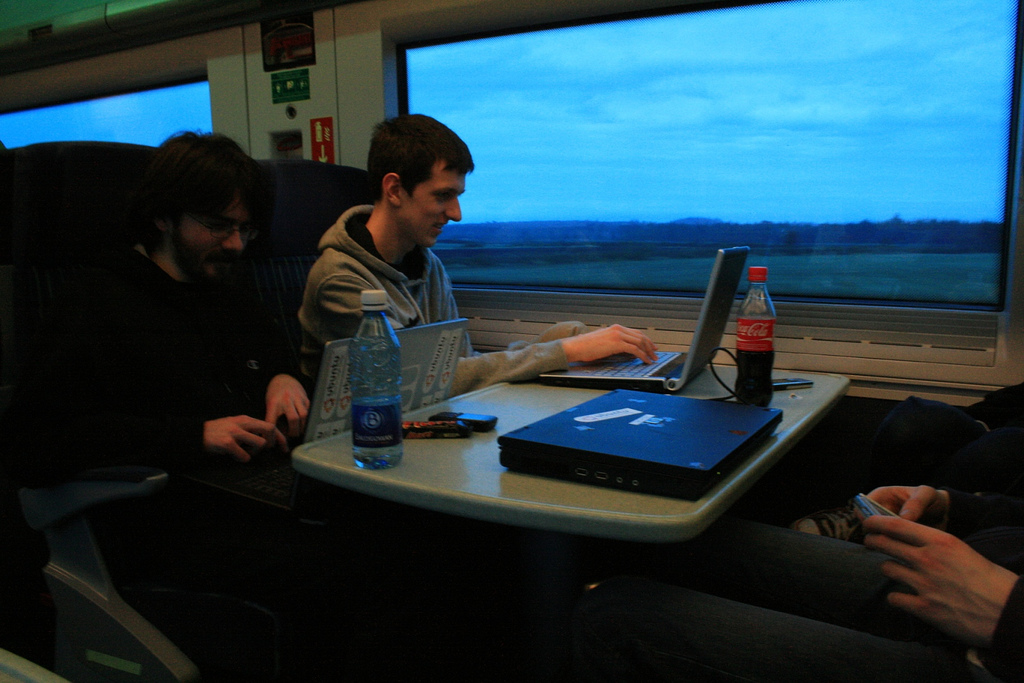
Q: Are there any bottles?
A: Yes, there is a bottle.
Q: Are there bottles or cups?
A: Yes, there is a bottle.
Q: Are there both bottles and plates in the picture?
A: No, there is a bottle but no plates.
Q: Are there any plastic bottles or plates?
A: Yes, there is a plastic bottle.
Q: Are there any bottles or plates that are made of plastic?
A: Yes, the bottle is made of plastic.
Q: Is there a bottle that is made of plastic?
A: Yes, there is a bottle that is made of plastic.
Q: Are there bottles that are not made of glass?
A: Yes, there is a bottle that is made of plastic.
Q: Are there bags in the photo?
A: No, there are no bags.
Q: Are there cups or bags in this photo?
A: No, there are no bags or cups.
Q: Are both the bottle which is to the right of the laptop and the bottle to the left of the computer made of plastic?
A: Yes, both the bottle and the bottle are made of plastic.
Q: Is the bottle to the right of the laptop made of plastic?
A: Yes, the bottle is made of plastic.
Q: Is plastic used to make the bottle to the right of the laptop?
A: Yes, the bottle is made of plastic.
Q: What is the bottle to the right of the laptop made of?
A: The bottle is made of plastic.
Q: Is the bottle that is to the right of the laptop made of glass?
A: No, the bottle is made of plastic.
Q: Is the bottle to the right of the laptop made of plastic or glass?
A: The bottle is made of plastic.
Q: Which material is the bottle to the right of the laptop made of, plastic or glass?
A: The bottle is made of plastic.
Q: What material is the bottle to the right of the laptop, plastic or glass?
A: The bottle is made of plastic.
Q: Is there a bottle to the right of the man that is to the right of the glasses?
A: Yes, there is a bottle to the right of the man.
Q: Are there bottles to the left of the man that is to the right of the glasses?
A: No, the bottle is to the right of the man.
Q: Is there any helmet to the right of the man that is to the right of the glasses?
A: No, there is a bottle to the right of the man.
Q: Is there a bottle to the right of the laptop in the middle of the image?
A: Yes, there is a bottle to the right of the laptop.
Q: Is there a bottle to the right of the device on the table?
A: Yes, there is a bottle to the right of the laptop.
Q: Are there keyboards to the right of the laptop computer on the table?
A: No, there is a bottle to the right of the laptop.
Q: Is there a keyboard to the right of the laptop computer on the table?
A: No, there is a bottle to the right of the laptop.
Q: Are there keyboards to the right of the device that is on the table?
A: No, there is a bottle to the right of the laptop.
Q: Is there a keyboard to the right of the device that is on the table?
A: No, there is a bottle to the right of the laptop.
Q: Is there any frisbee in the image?
A: No, there are no frisbees.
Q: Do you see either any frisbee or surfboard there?
A: No, there are no frisbees or surfboards.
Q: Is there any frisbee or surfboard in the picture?
A: No, there are no frisbees or surfboards.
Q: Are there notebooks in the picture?
A: No, there are no notebooks.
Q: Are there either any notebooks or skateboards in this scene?
A: No, there are no notebooks or skateboards.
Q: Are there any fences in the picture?
A: No, there are no fences.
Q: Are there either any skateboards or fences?
A: No, there are no fences or skateboards.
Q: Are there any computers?
A: Yes, there is a computer.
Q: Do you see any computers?
A: Yes, there is a computer.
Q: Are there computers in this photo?
A: Yes, there is a computer.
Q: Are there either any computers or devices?
A: Yes, there is a computer.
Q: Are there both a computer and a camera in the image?
A: No, there is a computer but no cameras.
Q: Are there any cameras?
A: No, there are no cameras.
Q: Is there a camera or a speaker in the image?
A: No, there are no cameras or speakers.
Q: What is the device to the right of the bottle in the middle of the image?
A: The device is a computer.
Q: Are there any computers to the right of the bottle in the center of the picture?
A: Yes, there is a computer to the right of the bottle.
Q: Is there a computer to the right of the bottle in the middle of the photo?
A: Yes, there is a computer to the right of the bottle.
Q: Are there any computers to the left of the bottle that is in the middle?
A: No, the computer is to the right of the bottle.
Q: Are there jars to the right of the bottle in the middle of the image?
A: No, there is a computer to the right of the bottle.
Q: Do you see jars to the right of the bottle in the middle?
A: No, there is a computer to the right of the bottle.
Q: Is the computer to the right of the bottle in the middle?
A: Yes, the computer is to the right of the bottle.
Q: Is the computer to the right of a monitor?
A: No, the computer is to the right of the bottle.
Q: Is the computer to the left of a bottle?
A: No, the computer is to the right of a bottle.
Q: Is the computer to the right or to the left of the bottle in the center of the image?
A: The computer is to the right of the bottle.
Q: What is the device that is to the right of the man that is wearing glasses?
A: The device is a computer.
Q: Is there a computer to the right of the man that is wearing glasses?
A: Yes, there is a computer to the right of the man.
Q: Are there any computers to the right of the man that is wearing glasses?
A: Yes, there is a computer to the right of the man.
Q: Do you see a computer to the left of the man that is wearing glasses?
A: No, the computer is to the right of the man.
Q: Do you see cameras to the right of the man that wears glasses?
A: No, there is a computer to the right of the man.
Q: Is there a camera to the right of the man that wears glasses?
A: No, there is a computer to the right of the man.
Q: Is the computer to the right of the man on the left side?
A: Yes, the computer is to the right of the man.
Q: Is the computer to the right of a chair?
A: No, the computer is to the right of the man.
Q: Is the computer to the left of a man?
A: No, the computer is to the right of a man.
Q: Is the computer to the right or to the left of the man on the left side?
A: The computer is to the right of the man.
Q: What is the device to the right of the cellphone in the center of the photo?
A: The device is a computer.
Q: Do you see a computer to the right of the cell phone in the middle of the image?
A: Yes, there is a computer to the right of the cellphone.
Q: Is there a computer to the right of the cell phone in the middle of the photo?
A: Yes, there is a computer to the right of the cellphone.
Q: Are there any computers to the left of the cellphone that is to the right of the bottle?
A: No, the computer is to the right of the cellphone.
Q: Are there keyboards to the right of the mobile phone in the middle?
A: No, there is a computer to the right of the cellphone.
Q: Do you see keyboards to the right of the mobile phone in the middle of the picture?
A: No, there is a computer to the right of the cellphone.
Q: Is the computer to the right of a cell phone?
A: Yes, the computer is to the right of a cell phone.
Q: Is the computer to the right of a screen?
A: No, the computer is to the right of a cell phone.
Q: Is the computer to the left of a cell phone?
A: No, the computer is to the right of a cell phone.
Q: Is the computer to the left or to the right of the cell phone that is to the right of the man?
A: The computer is to the right of the mobile phone.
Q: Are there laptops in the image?
A: Yes, there is a laptop.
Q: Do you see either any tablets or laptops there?
A: Yes, there is a laptop.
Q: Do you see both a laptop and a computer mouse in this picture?
A: No, there is a laptop but no computer mice.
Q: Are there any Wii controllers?
A: No, there are no Wii controllers.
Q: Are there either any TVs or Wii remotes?
A: No, there are no Wii remotes or tvs.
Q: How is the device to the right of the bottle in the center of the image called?
A: The device is a laptop.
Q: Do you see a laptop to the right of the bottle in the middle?
A: Yes, there is a laptop to the right of the bottle.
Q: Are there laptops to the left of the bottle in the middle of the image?
A: No, the laptop is to the right of the bottle.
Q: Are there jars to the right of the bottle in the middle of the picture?
A: No, there is a laptop to the right of the bottle.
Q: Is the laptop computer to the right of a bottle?
A: Yes, the laptop computer is to the right of a bottle.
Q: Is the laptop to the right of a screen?
A: No, the laptop is to the right of a bottle.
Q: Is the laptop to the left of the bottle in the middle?
A: No, the laptop is to the right of the bottle.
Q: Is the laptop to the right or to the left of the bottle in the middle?
A: The laptop is to the right of the bottle.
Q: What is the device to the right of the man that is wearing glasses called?
A: The device is a laptop.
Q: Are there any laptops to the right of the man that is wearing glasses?
A: Yes, there is a laptop to the right of the man.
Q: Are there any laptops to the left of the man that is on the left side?
A: No, the laptop is to the right of the man.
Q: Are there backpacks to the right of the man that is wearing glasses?
A: No, there is a laptop to the right of the man.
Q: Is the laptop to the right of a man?
A: Yes, the laptop is to the right of a man.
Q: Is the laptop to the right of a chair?
A: No, the laptop is to the right of a man.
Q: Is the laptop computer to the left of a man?
A: No, the laptop computer is to the right of a man.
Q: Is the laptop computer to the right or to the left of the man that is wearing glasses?
A: The laptop computer is to the right of the man.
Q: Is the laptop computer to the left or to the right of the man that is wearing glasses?
A: The laptop computer is to the right of the man.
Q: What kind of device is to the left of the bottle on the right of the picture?
A: The device is a laptop.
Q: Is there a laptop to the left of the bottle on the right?
A: Yes, there is a laptop to the left of the bottle.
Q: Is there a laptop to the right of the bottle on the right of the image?
A: No, the laptop is to the left of the bottle.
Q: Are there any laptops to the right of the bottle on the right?
A: No, the laptop is to the left of the bottle.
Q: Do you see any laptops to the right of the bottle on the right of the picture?
A: No, the laptop is to the left of the bottle.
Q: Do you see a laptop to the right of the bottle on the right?
A: No, the laptop is to the left of the bottle.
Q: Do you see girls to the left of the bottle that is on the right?
A: No, there is a laptop to the left of the bottle.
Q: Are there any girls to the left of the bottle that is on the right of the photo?
A: No, there is a laptop to the left of the bottle.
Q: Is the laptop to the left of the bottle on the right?
A: Yes, the laptop is to the left of the bottle.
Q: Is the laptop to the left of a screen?
A: No, the laptop is to the left of the bottle.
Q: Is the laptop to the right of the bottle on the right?
A: No, the laptop is to the left of the bottle.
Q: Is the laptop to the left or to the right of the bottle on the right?
A: The laptop is to the left of the bottle.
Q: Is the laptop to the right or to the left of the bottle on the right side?
A: The laptop is to the left of the bottle.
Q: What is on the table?
A: The laptop is on the table.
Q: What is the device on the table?
A: The device is a laptop.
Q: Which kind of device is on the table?
A: The device is a laptop.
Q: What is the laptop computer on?
A: The laptop computer is on the table.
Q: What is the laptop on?
A: The laptop computer is on the table.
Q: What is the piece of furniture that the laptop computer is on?
A: The piece of furniture is a table.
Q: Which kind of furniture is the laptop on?
A: The laptop computer is on the table.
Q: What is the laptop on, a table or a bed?
A: The laptop is on a table.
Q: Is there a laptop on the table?
A: Yes, there is a laptop on the table.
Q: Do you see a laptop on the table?
A: Yes, there is a laptop on the table.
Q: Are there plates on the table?
A: No, there is a laptop on the table.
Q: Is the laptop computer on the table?
A: Yes, the laptop computer is on the table.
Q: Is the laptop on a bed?
A: No, the laptop is on the table.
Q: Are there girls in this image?
A: No, there are no girls.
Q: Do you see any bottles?
A: Yes, there is a bottle.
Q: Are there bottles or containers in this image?
A: Yes, there is a bottle.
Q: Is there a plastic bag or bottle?
A: Yes, there is a plastic bottle.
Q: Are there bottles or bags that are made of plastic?
A: Yes, the bottle is made of plastic.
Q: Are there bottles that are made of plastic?
A: Yes, there is a bottle that is made of plastic.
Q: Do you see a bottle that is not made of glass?
A: Yes, there is a bottle that is made of plastic.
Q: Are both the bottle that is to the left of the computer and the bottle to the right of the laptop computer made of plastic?
A: Yes, both the bottle and the bottle are made of plastic.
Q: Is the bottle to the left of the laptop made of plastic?
A: Yes, the bottle is made of plastic.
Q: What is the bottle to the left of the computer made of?
A: The bottle is made of plastic.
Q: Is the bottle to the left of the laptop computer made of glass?
A: No, the bottle is made of plastic.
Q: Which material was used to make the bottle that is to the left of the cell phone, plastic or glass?
A: The bottle is made of plastic.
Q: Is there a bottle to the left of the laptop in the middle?
A: Yes, there is a bottle to the left of the laptop.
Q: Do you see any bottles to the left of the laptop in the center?
A: Yes, there is a bottle to the left of the laptop.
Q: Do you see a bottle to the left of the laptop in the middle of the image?
A: Yes, there is a bottle to the left of the laptop.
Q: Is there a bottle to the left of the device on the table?
A: Yes, there is a bottle to the left of the laptop.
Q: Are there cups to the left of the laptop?
A: No, there is a bottle to the left of the laptop.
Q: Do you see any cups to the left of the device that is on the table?
A: No, there is a bottle to the left of the laptop.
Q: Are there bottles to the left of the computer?
A: Yes, there is a bottle to the left of the computer.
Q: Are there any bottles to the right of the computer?
A: No, the bottle is to the left of the computer.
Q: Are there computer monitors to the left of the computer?
A: No, there is a bottle to the left of the computer.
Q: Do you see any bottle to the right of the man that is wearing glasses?
A: Yes, there is a bottle to the right of the man.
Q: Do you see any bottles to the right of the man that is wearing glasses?
A: Yes, there is a bottle to the right of the man.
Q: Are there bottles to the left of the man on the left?
A: No, the bottle is to the right of the man.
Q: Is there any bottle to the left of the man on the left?
A: No, the bottle is to the right of the man.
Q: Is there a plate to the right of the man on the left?
A: No, there is a bottle to the right of the man.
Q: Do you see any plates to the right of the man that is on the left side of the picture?
A: No, there is a bottle to the right of the man.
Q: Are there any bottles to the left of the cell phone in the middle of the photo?
A: Yes, there is a bottle to the left of the cell phone.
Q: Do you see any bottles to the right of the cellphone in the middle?
A: No, the bottle is to the left of the cellphone.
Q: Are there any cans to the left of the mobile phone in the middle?
A: No, there is a bottle to the left of the cellphone.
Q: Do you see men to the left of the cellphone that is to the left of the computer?
A: Yes, there is a man to the left of the mobile phone.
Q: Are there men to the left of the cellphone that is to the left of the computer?
A: Yes, there is a man to the left of the mobile phone.